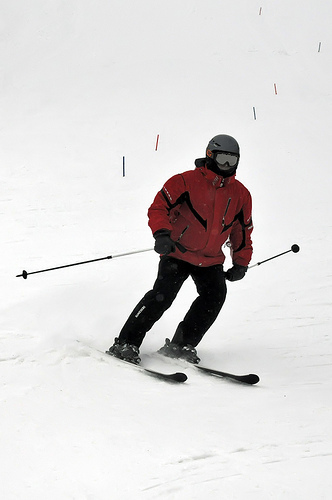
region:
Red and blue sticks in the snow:
[107, 73, 282, 183]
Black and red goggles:
[200, 139, 248, 175]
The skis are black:
[89, 331, 272, 390]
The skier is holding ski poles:
[19, 123, 306, 389]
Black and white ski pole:
[8, 238, 163, 285]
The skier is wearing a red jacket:
[142, 126, 271, 282]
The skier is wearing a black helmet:
[202, 138, 240, 179]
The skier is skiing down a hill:
[22, 124, 308, 396]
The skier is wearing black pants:
[104, 132, 250, 362]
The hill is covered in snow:
[18, 4, 325, 463]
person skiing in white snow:
[111, 134, 251, 387]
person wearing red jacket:
[168, 179, 244, 265]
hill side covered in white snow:
[22, 415, 86, 463]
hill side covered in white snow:
[97, 410, 147, 459]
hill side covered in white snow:
[174, 409, 225, 458]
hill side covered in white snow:
[224, 402, 270, 459]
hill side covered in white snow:
[278, 393, 330, 441]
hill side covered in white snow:
[262, 299, 308, 347]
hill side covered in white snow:
[25, 322, 62, 366]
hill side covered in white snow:
[75, 282, 114, 319]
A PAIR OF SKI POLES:
[14, 242, 313, 280]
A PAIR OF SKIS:
[72, 342, 265, 389]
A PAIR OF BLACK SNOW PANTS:
[116, 253, 229, 372]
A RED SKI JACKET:
[145, 163, 255, 269]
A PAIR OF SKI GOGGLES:
[210, 147, 242, 170]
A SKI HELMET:
[200, 132, 242, 166]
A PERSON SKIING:
[14, 123, 301, 388]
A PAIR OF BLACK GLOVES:
[152, 226, 255, 284]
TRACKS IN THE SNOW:
[144, 426, 323, 490]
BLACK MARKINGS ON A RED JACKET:
[157, 188, 249, 254]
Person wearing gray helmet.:
[196, 132, 244, 172]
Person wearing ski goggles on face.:
[201, 141, 245, 185]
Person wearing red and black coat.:
[141, 165, 221, 237]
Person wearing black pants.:
[123, 283, 238, 340]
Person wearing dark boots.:
[109, 334, 222, 371]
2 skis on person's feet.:
[95, 303, 283, 423]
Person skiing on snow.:
[82, 309, 258, 456]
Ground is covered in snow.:
[39, 315, 247, 495]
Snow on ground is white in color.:
[35, 398, 171, 498]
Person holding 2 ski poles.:
[59, 203, 327, 318]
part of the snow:
[274, 272, 285, 288]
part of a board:
[244, 373, 245, 375]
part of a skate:
[117, 344, 147, 357]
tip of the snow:
[100, 411, 120, 437]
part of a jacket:
[198, 195, 217, 229]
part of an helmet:
[229, 148, 240, 156]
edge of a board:
[230, 371, 237, 377]